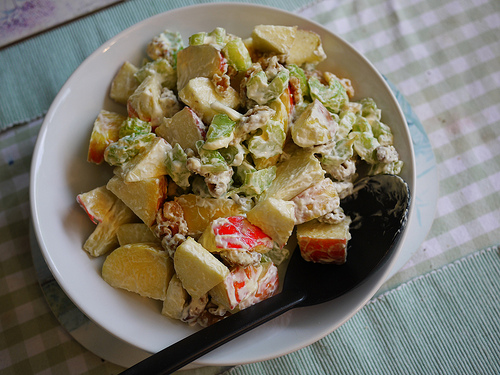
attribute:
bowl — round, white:
[30, 2, 417, 366]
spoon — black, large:
[118, 171, 410, 374]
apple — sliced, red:
[296, 215, 352, 265]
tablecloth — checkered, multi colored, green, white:
[0, 1, 499, 374]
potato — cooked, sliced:
[101, 240, 174, 300]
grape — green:
[223, 41, 252, 74]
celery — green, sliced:
[249, 120, 285, 158]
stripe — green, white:
[368, 1, 499, 216]